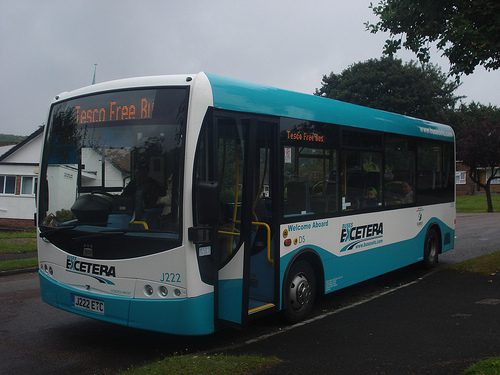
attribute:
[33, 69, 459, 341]
bus — blue, light blue, white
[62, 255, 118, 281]
excetera — black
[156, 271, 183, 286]
j222 — blue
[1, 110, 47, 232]
house — in background, white, small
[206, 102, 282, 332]
bus door — open, opened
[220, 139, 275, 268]
hand rails — yellow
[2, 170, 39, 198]
windows — white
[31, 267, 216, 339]
front bumper — blue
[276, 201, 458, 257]
stripe — white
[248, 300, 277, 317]
step — yellow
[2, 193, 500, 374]
grass — green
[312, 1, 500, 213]
trees — in background